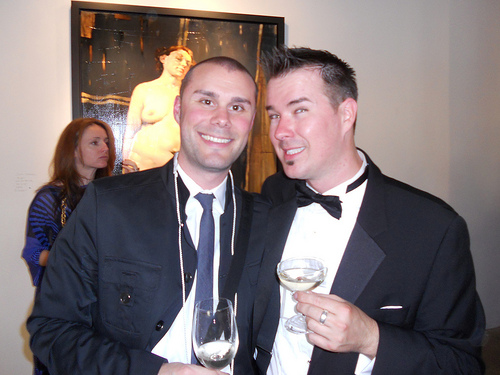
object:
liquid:
[194, 339, 235, 369]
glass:
[190, 297, 240, 371]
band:
[319, 311, 329, 324]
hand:
[292, 288, 371, 355]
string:
[173, 151, 238, 307]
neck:
[178, 147, 229, 189]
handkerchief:
[150, 262, 199, 363]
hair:
[35, 118, 117, 212]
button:
[155, 319, 165, 332]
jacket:
[23, 158, 270, 374]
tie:
[189, 191, 216, 367]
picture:
[67, 1, 286, 195]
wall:
[0, 1, 452, 373]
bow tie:
[295, 182, 342, 221]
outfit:
[19, 178, 99, 287]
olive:
[295, 276, 306, 282]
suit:
[251, 146, 487, 374]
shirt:
[260, 149, 375, 375]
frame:
[68, 0, 284, 194]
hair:
[263, 46, 357, 113]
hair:
[181, 55, 259, 107]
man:
[251, 45, 488, 375]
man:
[24, 56, 274, 375]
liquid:
[275, 267, 325, 292]